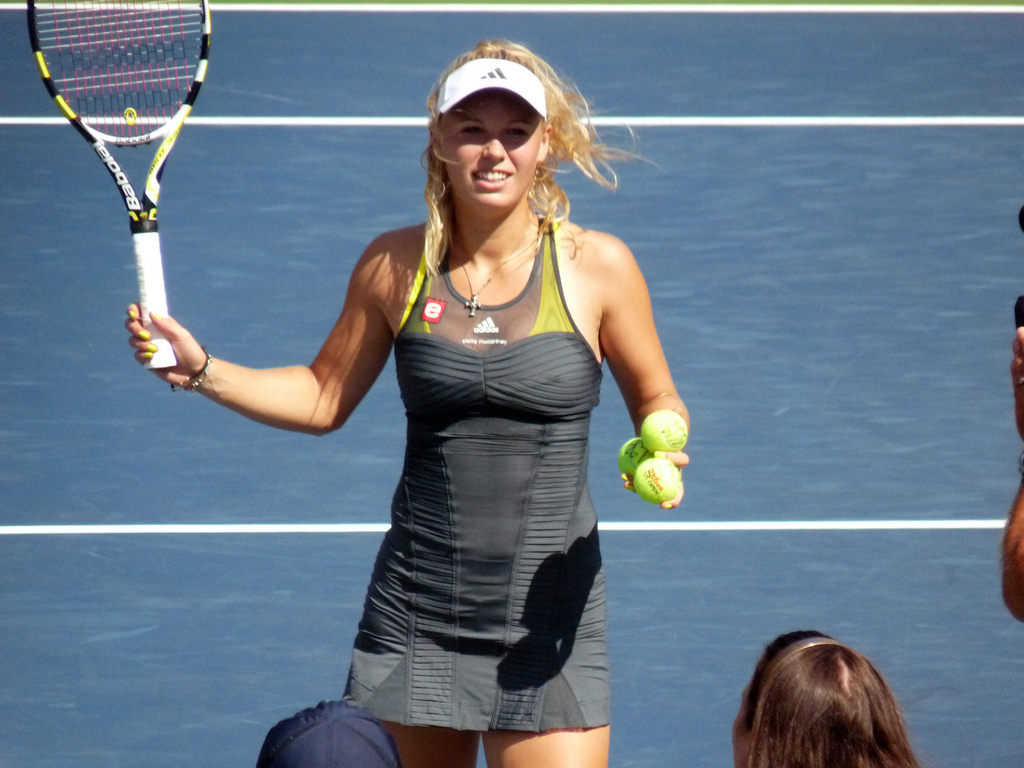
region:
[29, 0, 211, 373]
the woman holds a racket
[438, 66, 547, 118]
the woman wears a visor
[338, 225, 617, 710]
the woman wears a black dress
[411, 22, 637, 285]
the woman is blonde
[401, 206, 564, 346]
the woman has a yellow bra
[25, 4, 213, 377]
the racket is white and black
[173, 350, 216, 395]
woman wears a bracelet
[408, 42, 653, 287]
the woman has long hair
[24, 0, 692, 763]
tennis player holding a racket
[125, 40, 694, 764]
tennis player holding tennis balls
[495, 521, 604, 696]
shadow of hand and tennis balls on clothes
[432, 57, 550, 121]
white visor on tennis players head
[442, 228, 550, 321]
cross necklace around woman's neck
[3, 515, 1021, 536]
white boundary lines on tennis court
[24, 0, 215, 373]
black, white and yellow tennis racket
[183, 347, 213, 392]
watch around woman's wrist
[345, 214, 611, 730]
gray and yellow tennis outfit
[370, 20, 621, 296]
the woman has blonde hair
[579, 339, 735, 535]
the woman is holding balls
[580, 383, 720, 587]
the balls are green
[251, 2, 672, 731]
the woman is wearing a dress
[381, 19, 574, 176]
the woman is wearing a visor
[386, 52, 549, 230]
the woman is smiling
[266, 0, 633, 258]
the visor is white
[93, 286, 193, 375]
the nails are painted yellow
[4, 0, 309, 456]
the woman is holding a tennis racket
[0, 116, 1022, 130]
white line is on a court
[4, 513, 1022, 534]
white line is on a court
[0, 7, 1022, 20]
white line is on a court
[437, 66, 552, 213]
woman has a head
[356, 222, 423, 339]
woman has a shoulder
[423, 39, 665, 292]
woman has blonde hair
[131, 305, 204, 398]
player has a hand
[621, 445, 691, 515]
player has a hand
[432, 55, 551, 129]
white visor with dark insignia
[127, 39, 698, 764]
woman wearing a dark gray outfit over yellow sports bra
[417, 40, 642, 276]
blonde hair under a white sun visor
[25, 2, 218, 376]
black and white racket with a white handle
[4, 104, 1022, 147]
white line painted on blue tennis court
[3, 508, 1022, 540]
white line painted on blue tennis court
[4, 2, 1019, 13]
white line painted on blue tennis court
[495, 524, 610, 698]
black shadow on a gray outfit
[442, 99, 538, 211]
woman smiling with black shadow over her eyes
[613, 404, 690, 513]
woman's left hand holding green tennis balls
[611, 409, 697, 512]
Trio of tennis balls in woman's hand.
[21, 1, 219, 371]
Yellow, black and white tennis racket.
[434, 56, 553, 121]
White visor with logo.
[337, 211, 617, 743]
Black and yellow tennis dress.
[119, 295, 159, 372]
Yellow painted fingernails on woman's hand.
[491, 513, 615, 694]
Shadow from hand on dress.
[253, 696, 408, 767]
Blue baseball cap on head.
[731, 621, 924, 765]
Back of woman's head.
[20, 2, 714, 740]
Blonde woman's holding tennis racket.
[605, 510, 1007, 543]
White stripe on ground.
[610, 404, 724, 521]
balls are green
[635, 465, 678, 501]
A yellow tennis ball.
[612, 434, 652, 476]
A yellow tennis ball.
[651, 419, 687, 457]
A yellow tennis ball.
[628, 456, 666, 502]
A yellow tennis ball.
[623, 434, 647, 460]
A yellow tennis ball.